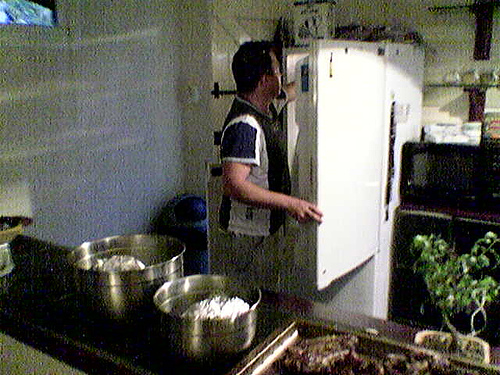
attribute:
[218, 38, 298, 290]
man — cooking, asian, making dinner, in the kitchen, preparing a meal, reaching, light skinned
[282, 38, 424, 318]
refrigerator — white, open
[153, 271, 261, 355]
pot — stainless steel, large, silver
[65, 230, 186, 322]
pot — stainless steel, large, silver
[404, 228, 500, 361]
bonsai tree — small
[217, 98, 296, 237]
shirt — blue, white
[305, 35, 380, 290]
refrigerator door — open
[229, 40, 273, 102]
hair — black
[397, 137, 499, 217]
microwave oven — black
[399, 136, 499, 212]
microwave — black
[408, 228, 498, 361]
tree — small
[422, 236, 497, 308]
leaves — green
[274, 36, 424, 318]
fridge — white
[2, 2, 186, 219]
wall — white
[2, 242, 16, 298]
container — metallic